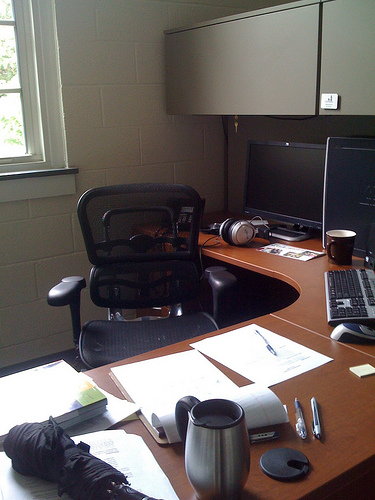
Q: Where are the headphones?
A: In front of the computer.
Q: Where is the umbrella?
A: In the lower left corner.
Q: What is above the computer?
A: Cabinets.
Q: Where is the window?
A: Behind the desk.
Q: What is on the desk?
A: An umbrella.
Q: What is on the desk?
A: A notepad.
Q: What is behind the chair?
A: A window.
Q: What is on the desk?
A: A silver mug.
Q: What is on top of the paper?
A: An umbrella.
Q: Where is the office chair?
A: Next to the desk.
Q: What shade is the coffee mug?
A: Silver.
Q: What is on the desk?
A: Paper.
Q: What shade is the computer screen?
A: Black.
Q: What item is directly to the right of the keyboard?
A: A mouse.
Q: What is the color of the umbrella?
A: Black.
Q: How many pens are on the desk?
A: Three.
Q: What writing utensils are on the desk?
A: Pens.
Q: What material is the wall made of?
A: Concrete.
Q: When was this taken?
A: Day time.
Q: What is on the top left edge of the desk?
A: Umbrella.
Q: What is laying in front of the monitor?
A: Headphones.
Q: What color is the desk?
A: Brown.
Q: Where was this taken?
A: Office.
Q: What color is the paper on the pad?
A: White.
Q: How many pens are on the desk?
A: 3.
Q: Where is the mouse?
A: Next to the keyboard.